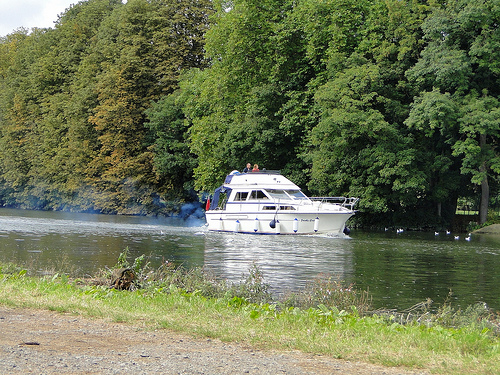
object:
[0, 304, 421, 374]
road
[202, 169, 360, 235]
boat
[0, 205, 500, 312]
river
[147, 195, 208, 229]
smoke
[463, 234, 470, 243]
ducks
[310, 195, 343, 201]
rails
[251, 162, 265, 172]
people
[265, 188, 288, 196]
windows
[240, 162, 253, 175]
people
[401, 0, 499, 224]
trees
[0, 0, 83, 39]
sky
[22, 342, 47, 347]
rocks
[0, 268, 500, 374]
ground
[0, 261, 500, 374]
grass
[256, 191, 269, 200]
window